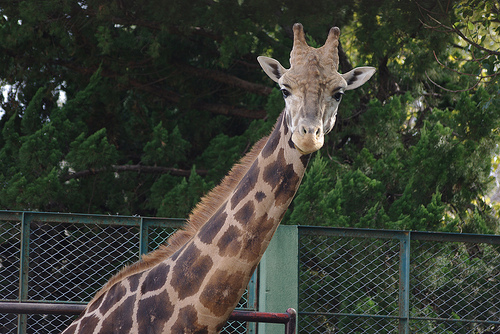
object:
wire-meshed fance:
[406, 227, 498, 332]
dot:
[198, 268, 246, 318]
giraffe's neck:
[166, 111, 311, 262]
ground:
[428, 142, 453, 162]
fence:
[0, 209, 500, 334]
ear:
[343, 66, 377, 90]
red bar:
[0, 303, 298, 334]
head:
[257, 23, 376, 155]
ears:
[257, 55, 287, 83]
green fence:
[0, 208, 500, 334]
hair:
[92, 111, 282, 300]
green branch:
[1, 1, 496, 232]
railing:
[0, 302, 295, 334]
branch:
[0, 0, 500, 234]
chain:
[0, 220, 500, 334]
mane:
[85, 109, 285, 308]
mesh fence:
[0, 219, 500, 334]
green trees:
[1, 0, 500, 333]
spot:
[254, 191, 267, 202]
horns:
[293, 23, 341, 49]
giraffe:
[59, 23, 375, 334]